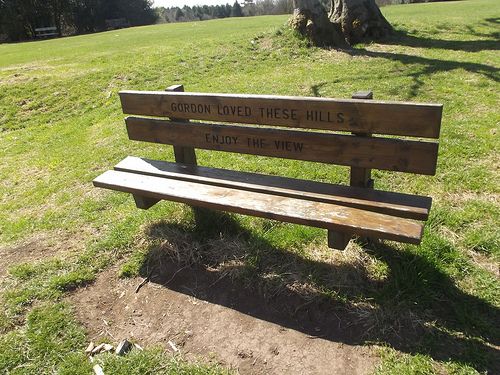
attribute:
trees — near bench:
[122, 2, 240, 29]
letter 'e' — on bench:
[284, 139, 295, 155]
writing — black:
[167, 96, 347, 156]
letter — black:
[220, 102, 230, 122]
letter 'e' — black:
[234, 104, 246, 119]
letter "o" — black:
[190, 96, 206, 116]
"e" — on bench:
[271, 104, 281, 122]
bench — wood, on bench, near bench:
[90, 82, 443, 249]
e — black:
[288, 111, 297, 120]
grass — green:
[57, 52, 189, 89]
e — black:
[274, 105, 280, 122]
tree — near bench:
[288, 1, 393, 41]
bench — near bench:
[99, 83, 447, 276]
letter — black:
[209, 89, 301, 161]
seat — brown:
[90, 151, 432, 248]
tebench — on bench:
[87, 79, 447, 260]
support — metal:
[302, 79, 394, 286]